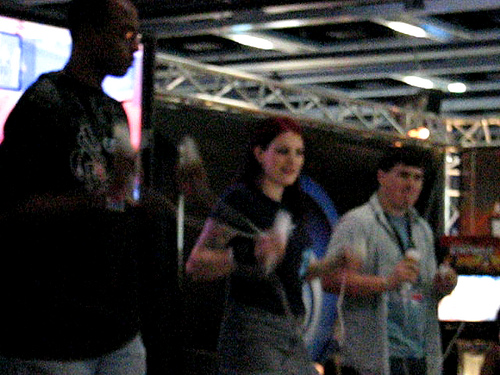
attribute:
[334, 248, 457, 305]
hands — Pair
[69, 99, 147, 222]
brandings — on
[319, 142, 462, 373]
person — inside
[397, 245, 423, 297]
controller — white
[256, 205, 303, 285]
controller — white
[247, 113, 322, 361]
person — inside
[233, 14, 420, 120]
structures — steel 